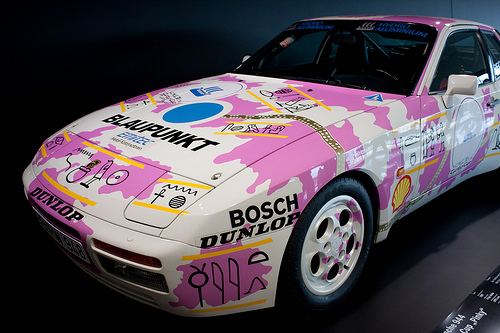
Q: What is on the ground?
A: A car.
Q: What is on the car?
A: Wheels.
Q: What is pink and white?
A: The car.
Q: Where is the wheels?
A: On the car.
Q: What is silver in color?
A: The rim.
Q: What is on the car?
A: Writing.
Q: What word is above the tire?
A: Dunlop.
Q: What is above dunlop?
A: Bosch.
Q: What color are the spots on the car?
A: Pink.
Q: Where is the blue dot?
A: On the hood.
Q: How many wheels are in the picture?
A: One.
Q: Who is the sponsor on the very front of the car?
A: Dunlop.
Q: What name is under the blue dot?
A: Blaupunkt.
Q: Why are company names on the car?
A: They are sponsors.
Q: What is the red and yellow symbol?
A: Shell Oil.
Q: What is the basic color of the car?
A: White.